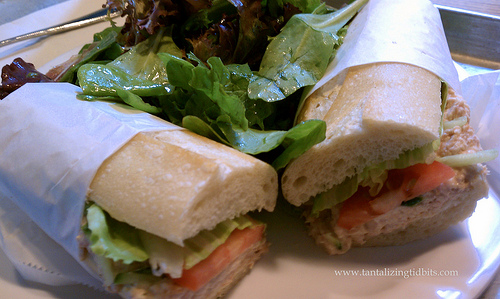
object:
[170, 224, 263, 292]
tomato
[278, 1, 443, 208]
bread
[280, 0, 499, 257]
sandwich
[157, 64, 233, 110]
greens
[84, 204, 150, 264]
lettuce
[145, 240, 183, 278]
onion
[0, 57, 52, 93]
leaf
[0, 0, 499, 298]
plate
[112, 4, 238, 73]
salad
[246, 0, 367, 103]
leaves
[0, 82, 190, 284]
wrapping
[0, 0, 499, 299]
lunch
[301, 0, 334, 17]
spinach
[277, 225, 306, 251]
shadow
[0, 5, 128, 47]
handle